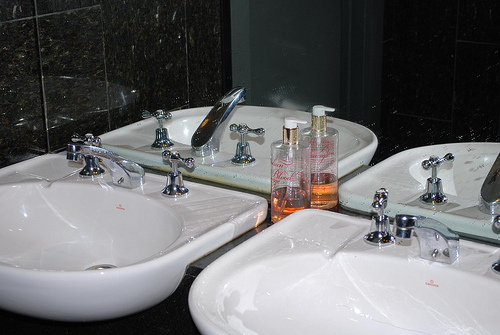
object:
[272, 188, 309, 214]
soap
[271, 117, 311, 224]
bottle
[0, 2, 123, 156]
wall tile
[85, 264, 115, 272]
sink drain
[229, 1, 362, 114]
door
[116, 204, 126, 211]
letters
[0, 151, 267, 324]
sink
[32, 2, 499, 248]
mirror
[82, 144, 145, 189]
faucet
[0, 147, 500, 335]
counter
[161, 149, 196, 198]
handle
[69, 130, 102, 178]
handle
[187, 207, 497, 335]
sink